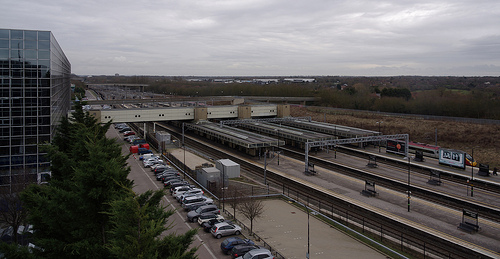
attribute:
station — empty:
[104, 116, 445, 177]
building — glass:
[1, 29, 71, 195]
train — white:
[408, 142, 476, 167]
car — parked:
[130, 142, 151, 153]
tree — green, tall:
[105, 191, 203, 258]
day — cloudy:
[0, 2, 499, 256]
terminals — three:
[186, 119, 385, 156]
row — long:
[116, 123, 273, 257]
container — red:
[131, 142, 151, 151]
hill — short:
[393, 74, 428, 81]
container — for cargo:
[216, 159, 240, 179]